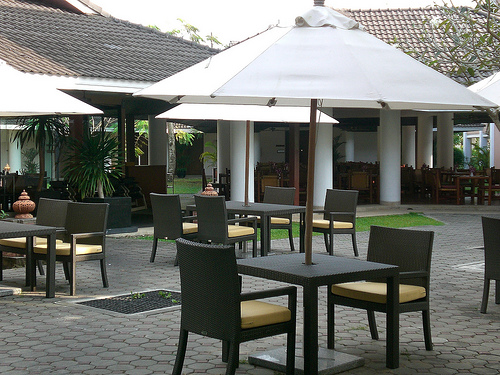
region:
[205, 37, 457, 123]
The umbrella is white.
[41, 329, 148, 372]
The floor is grey.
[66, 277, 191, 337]
There is a vent in the floor.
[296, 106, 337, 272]
The umbrella pole is brown.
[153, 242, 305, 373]
The chair is black.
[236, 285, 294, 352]
The chair cushion is tan.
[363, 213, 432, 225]
The grass is green.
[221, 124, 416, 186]
The poles on the building are white.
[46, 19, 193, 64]
The roof is brown.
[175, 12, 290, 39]
The sky is white.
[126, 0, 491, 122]
An umbrella is above the table.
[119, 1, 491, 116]
The umbrella is large.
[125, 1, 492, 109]
The umbrella is white.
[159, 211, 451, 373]
Two chairs are with the table.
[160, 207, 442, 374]
The chairs are empty.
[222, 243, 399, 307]
The table is empty.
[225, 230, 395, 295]
The table is black.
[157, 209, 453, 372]
The chairs are tan and black.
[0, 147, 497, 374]
The cafe is empty.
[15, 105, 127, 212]
Palm trees are in the background.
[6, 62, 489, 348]
empty outdoor eating area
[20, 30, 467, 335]
white umbrellas over black tables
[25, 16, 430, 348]
round umbrellas over square and rectangular tables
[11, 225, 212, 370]
circular bricks on outdoor patio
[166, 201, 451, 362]
dark seats with yellow cushions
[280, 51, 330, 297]
pole connecting umbrella to table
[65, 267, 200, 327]
metal panel in ground with weeds on top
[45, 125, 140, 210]
plant with long and spiky leaves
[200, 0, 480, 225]
round and white columns under a roof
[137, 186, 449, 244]
rectangular patch of grass behind table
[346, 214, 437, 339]
A black chair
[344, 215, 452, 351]
A black chair with a yellow cushion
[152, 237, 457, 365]
Two black chairs with yellow cushions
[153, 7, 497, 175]
A big white umbrella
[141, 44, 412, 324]
A white umbrella over a table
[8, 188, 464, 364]
Black chairs on a brick patio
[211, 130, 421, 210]
Three white pillars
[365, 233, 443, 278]
The back of a chair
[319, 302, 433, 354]
The legs of a chair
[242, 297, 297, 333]
The seat of a chair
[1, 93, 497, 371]
The cafe is empty.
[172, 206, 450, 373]
The table has two chairs.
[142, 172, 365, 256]
The table has four chairs.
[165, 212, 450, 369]
The chairs are black and tan.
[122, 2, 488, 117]
A large umbrella shades the table.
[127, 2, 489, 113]
The umbrella is white.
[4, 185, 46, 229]
Decorative urns are in the cafe.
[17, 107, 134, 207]
Palm trees are in the cafe.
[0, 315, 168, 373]
The ground is grey.